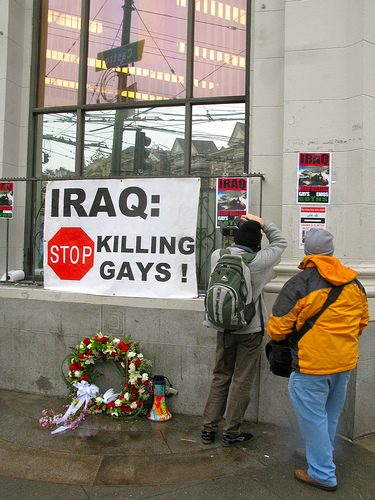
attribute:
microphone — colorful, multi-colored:
[148, 376, 177, 422]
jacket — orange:
[266, 254, 369, 375]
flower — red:
[83, 338, 90, 345]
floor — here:
[1, 387, 375, 499]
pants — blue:
[289, 373, 350, 487]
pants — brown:
[204, 331, 263, 434]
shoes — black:
[202, 431, 252, 445]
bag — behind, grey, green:
[205, 249, 257, 330]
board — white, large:
[44, 177, 202, 298]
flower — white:
[114, 399, 121, 407]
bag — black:
[266, 286, 341, 377]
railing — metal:
[1, 172, 263, 181]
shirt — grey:
[204, 221, 288, 335]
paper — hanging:
[216, 177, 250, 228]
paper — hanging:
[1, 180, 13, 219]